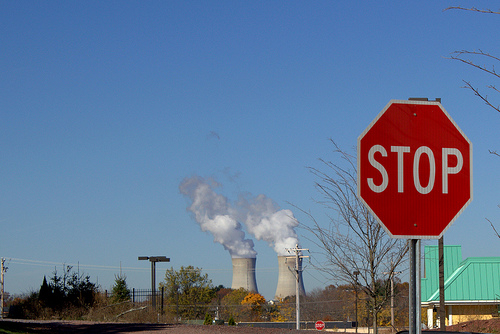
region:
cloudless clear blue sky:
[2, 5, 317, 168]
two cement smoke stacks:
[216, 240, 311, 307]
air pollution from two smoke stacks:
[167, 180, 312, 262]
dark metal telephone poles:
[117, 241, 178, 316]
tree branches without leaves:
[300, 140, 385, 327]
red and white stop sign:
[340, 95, 476, 245]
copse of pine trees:
[20, 250, 100, 320]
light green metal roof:
[415, 240, 495, 305]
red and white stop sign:
[305, 315, 327, 330]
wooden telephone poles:
[271, 241, 316, 331]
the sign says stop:
[304, 78, 494, 241]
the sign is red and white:
[330, 63, 470, 210]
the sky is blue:
[20, 13, 469, 250]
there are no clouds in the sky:
[3, 7, 468, 268]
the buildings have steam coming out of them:
[172, 176, 353, 313]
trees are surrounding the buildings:
[25, 253, 455, 319]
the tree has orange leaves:
[230, 283, 290, 331]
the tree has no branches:
[298, 166, 446, 299]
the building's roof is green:
[403, 241, 484, 304]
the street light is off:
[125, 231, 179, 314]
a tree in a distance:
[238, 287, 263, 324]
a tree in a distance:
[223, 287, 252, 325]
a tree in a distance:
[161, 260, 216, 325]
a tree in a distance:
[294, 139, 401, 329]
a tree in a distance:
[107, 270, 136, 314]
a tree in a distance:
[33, 267, 56, 309]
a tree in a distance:
[53, 257, 91, 316]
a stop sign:
[359, 86, 466, 328]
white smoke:
[241, 190, 309, 257]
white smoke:
[181, 148, 260, 257]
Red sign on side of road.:
[353, 76, 456, 268]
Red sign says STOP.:
[353, 191, 480, 316]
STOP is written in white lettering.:
[357, 82, 496, 267]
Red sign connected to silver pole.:
[388, 152, 472, 294]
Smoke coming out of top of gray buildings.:
[181, 133, 404, 331]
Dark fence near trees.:
[107, 274, 192, 319]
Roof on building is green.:
[438, 226, 493, 321]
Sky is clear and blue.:
[76, 52, 309, 128]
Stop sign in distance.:
[299, 281, 344, 331]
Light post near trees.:
[118, 250, 202, 309]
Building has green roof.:
[448, 236, 492, 304]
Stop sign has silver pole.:
[381, 240, 432, 330]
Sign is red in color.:
[357, 107, 494, 305]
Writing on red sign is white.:
[352, 91, 437, 298]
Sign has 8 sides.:
[344, 106, 489, 269]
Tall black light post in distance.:
[133, 244, 191, 324]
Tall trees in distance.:
[28, 257, 118, 327]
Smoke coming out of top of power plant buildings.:
[188, 167, 342, 322]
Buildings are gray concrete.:
[204, 236, 371, 331]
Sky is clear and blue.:
[62, 105, 158, 213]